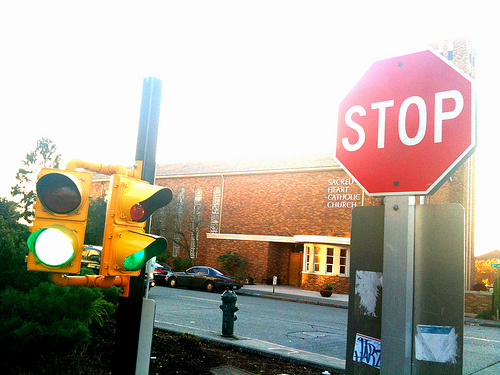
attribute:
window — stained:
[205, 185, 223, 237]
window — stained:
[186, 183, 202, 266]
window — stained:
[167, 182, 184, 269]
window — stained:
[152, 202, 165, 240]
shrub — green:
[1, 196, 123, 367]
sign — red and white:
[333, 47, 477, 196]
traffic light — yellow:
[23, 155, 175, 302]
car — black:
[162, 260, 243, 294]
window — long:
[184, 183, 203, 269]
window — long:
[168, 185, 186, 270]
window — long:
[153, 201, 163, 236]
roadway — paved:
[154, 278, 496, 373]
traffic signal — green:
[28, 226, 78, 265]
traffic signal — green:
[119, 243, 148, 272]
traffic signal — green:
[118, 243, 154, 277]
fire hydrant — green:
[215, 286, 239, 340]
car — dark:
[159, 257, 243, 292]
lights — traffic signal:
[22, 157, 174, 302]